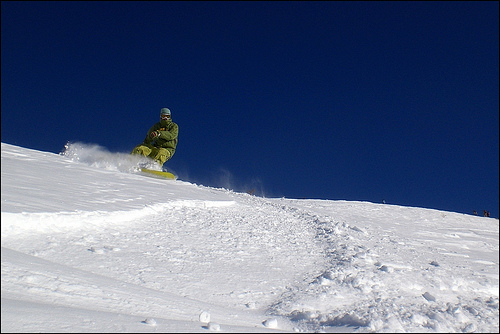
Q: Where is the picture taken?
A: Ski slope.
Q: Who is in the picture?
A: A man.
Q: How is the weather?
A: Sunny.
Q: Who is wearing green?
A: The man.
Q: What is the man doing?
A: Snowboarding.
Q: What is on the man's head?
A: A helmet.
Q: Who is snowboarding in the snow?
A: A man.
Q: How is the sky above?
A: Dark blue.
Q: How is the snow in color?
A: White powder.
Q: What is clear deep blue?
A: The sky.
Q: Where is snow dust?
A: Behind snowboarder.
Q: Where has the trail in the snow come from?
A: The snowboarder.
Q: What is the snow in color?
A: White and clear.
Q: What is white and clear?
A: The snow.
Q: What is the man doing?
A: Snowboarding.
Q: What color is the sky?
A: Blue.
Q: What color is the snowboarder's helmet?
A: Blue.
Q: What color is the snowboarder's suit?
A: Green.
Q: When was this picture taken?
A: Daytime.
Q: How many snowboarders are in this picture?
A: One.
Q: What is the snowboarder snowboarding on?
A: Snow.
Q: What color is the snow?
A: White.